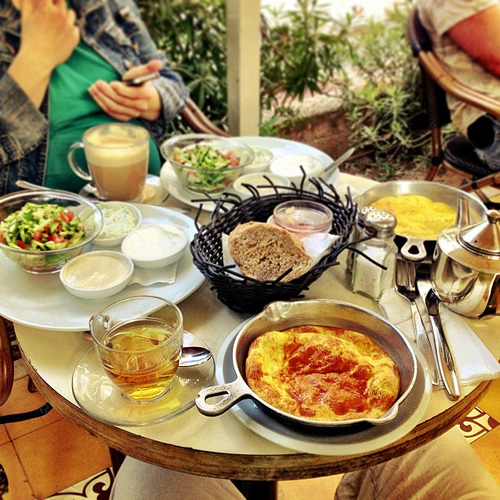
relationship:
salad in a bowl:
[12, 206, 75, 249] [9, 218, 71, 290]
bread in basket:
[227, 218, 307, 270] [183, 173, 363, 306]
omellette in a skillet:
[260, 332, 379, 412] [199, 307, 425, 453]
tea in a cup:
[122, 338, 162, 399] [65, 306, 189, 417]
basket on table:
[183, 173, 363, 306] [31, 336, 329, 494]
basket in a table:
[183, 173, 363, 306] [31, 336, 329, 494]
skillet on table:
[199, 307, 425, 453] [31, 336, 329, 494]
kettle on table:
[437, 191, 499, 329] [31, 336, 329, 494]